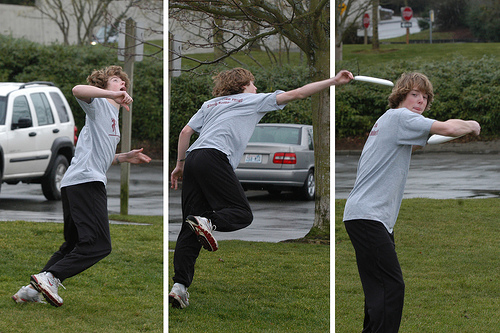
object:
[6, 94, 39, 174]
door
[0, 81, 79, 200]
car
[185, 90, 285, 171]
shirt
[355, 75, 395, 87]
frisbee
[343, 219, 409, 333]
pants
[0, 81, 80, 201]
suv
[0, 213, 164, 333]
green grass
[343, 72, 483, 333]
boy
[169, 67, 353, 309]
boy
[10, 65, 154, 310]
boy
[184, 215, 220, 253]
shoe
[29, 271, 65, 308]
shoe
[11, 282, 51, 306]
shoe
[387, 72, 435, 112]
hair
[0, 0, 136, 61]
branches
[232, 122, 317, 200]
car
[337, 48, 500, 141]
green bush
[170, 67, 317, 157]
green bush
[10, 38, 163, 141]
green bush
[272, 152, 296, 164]
light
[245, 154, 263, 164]
license plate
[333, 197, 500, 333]
grass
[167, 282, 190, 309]
shoes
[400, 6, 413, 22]
stop sign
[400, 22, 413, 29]
sign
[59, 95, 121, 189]
shirt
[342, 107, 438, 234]
shirt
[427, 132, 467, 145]
frisbee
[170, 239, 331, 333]
ground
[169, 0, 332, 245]
trees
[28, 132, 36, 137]
handle